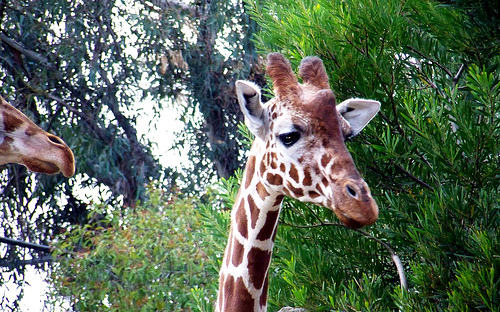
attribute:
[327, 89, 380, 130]
ear — white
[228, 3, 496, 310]
tree — green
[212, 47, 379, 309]
giraffe — tall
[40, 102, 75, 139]
leaves — dark green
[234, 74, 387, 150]
ears — white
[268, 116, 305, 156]
giraffe's eye — black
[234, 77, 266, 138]
ear — perky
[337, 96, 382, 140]
ear — perky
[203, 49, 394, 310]
giraffe — tall